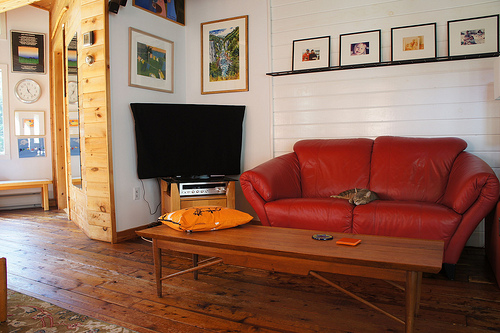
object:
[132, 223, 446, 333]
wood table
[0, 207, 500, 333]
floor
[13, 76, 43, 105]
clock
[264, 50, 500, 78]
shelf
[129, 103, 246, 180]
tv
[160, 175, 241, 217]
table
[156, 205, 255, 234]
pillow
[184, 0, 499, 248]
wall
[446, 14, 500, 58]
picture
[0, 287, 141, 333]
carpet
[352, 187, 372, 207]
head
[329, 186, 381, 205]
cat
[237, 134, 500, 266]
couch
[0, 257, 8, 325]
wood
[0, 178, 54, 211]
bench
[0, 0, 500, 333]
house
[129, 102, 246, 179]
tv screen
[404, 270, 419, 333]
legs